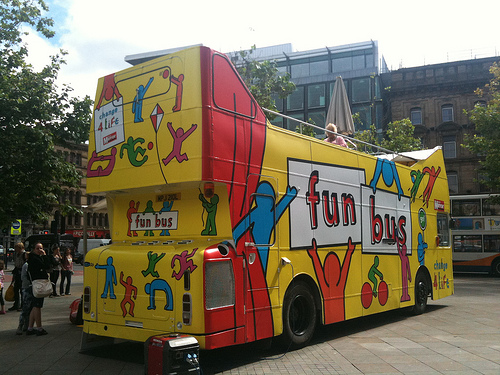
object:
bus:
[72, 46, 455, 358]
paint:
[114, 126, 148, 180]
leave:
[1, 88, 15, 112]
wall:
[395, 106, 407, 120]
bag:
[26, 275, 58, 298]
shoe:
[24, 321, 53, 343]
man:
[9, 238, 30, 311]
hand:
[39, 249, 47, 255]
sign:
[5, 213, 25, 237]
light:
[80, 204, 91, 255]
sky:
[155, 18, 179, 30]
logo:
[287, 156, 415, 256]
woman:
[21, 240, 52, 337]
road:
[358, 323, 408, 347]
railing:
[268, 107, 319, 130]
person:
[319, 120, 348, 149]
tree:
[1, 73, 37, 228]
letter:
[338, 191, 359, 229]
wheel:
[278, 280, 320, 346]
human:
[127, 77, 155, 123]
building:
[407, 74, 451, 111]